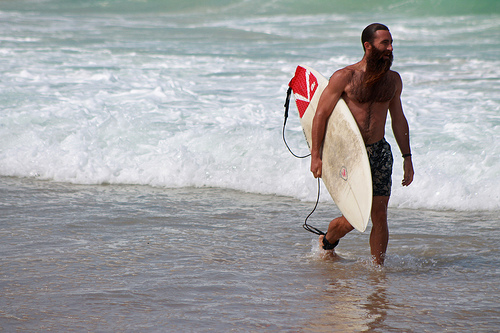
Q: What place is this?
A: It is a beach.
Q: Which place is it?
A: It is a beach.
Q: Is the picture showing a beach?
A: Yes, it is showing a beach.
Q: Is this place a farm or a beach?
A: It is a beach.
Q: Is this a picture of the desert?
A: No, the picture is showing the beach.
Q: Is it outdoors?
A: Yes, it is outdoors.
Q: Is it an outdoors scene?
A: Yes, it is outdoors.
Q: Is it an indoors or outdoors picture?
A: It is outdoors.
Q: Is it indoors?
A: No, it is outdoors.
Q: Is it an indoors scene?
A: No, it is outdoors.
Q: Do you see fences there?
A: No, there are no fences.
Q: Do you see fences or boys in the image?
A: No, there are no fences or boys.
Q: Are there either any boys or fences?
A: No, there are no fences or boys.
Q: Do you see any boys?
A: No, there are no boys.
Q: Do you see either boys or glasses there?
A: No, there are no boys or glasses.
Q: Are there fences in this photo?
A: No, there are no fences.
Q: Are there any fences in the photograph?
A: No, there are no fences.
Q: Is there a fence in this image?
A: No, there are no fences.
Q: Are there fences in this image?
A: No, there are no fences.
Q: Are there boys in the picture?
A: No, there are no boys.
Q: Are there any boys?
A: No, there are no boys.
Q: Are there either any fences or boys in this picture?
A: No, there are no boys or fences.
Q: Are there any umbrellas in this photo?
A: No, there are no umbrellas.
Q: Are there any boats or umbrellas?
A: No, there are no umbrellas or boats.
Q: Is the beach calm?
A: Yes, the beach is calm.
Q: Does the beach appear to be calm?
A: Yes, the beach is calm.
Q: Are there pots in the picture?
A: No, there are no pots.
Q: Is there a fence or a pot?
A: No, there are no pots or fences.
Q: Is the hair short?
A: Yes, the hair is short.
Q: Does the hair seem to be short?
A: Yes, the hair is short.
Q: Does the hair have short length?
A: Yes, the hair is short.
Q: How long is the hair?
A: The hair is short.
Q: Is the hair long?
A: No, the hair is short.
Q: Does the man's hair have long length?
A: No, the hair is short.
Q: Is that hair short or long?
A: The hair is short.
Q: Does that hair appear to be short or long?
A: The hair is short.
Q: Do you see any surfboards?
A: Yes, there is a surfboard.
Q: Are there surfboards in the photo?
A: Yes, there is a surfboard.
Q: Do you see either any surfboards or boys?
A: Yes, there is a surfboard.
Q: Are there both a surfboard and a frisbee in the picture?
A: No, there is a surfboard but no frisbees.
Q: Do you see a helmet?
A: No, there are no helmets.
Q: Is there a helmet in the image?
A: No, there are no helmets.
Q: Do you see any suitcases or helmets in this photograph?
A: No, there are no helmets or suitcases.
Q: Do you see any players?
A: No, there are no players.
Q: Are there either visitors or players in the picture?
A: No, there are no players or visitors.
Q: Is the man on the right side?
A: Yes, the man is on the right of the image.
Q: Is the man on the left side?
A: No, the man is on the right of the image.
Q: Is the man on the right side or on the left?
A: The man is on the right of the image.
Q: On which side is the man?
A: The man is on the right of the image.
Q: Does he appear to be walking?
A: Yes, the man is walking.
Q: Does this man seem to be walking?
A: Yes, the man is walking.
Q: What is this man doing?
A: The man is walking.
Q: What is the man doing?
A: The man is walking.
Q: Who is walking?
A: The man is walking.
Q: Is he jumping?
A: No, the man is walking.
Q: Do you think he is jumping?
A: No, the man is walking.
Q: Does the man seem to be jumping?
A: No, the man is walking.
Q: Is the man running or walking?
A: The man is walking.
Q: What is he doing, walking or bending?
A: The man is walking.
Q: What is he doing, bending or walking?
A: The man is walking.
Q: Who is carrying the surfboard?
A: The man is carrying the surfboard.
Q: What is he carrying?
A: The man is carrying a surfboard.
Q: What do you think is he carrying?
A: The man is carrying a surfboard.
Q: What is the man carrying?
A: The man is carrying a surfboard.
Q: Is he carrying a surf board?
A: Yes, the man is carrying a surf board.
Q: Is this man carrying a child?
A: No, the man is carrying a surf board.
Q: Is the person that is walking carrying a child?
A: No, the man is carrying a surf board.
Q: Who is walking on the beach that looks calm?
A: The man is walking on the beach.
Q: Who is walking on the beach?
A: The man is walking on the beach.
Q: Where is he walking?
A: The man is walking on the beach.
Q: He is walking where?
A: The man is walking on the beach.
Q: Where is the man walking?
A: The man is walking on the beach.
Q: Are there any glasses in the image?
A: No, there are no glasses.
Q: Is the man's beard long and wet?
A: Yes, the beard is long and wet.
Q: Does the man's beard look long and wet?
A: Yes, the beard is long and wet.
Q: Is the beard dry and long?
A: No, the beard is long but wet.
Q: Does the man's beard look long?
A: Yes, the beard is long.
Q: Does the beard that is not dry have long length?
A: Yes, the beard is long.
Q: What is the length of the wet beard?
A: The beard is long.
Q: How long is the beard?
A: The beard is long.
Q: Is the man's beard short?
A: No, the beard is long.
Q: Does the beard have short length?
A: No, the beard is long.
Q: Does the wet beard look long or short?
A: The beard is long.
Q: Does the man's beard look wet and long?
A: Yes, the beard is wet and long.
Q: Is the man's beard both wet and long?
A: Yes, the beard is wet and long.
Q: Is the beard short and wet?
A: No, the beard is wet but long.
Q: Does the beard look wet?
A: Yes, the beard is wet.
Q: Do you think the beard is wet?
A: Yes, the beard is wet.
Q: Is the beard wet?
A: Yes, the beard is wet.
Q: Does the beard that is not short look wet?
A: Yes, the beard is wet.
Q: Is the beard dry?
A: No, the beard is wet.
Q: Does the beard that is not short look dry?
A: No, the beard is wet.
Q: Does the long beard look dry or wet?
A: The beard is wet.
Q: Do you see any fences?
A: No, there are no fences.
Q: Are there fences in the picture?
A: No, there are no fences.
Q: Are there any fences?
A: No, there are no fences.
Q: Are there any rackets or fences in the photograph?
A: No, there are no fences or rackets.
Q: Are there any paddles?
A: No, there are no paddles.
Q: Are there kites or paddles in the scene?
A: No, there are no paddles or kites.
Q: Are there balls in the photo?
A: No, there are no balls.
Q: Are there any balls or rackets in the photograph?
A: No, there are no balls or rackets.